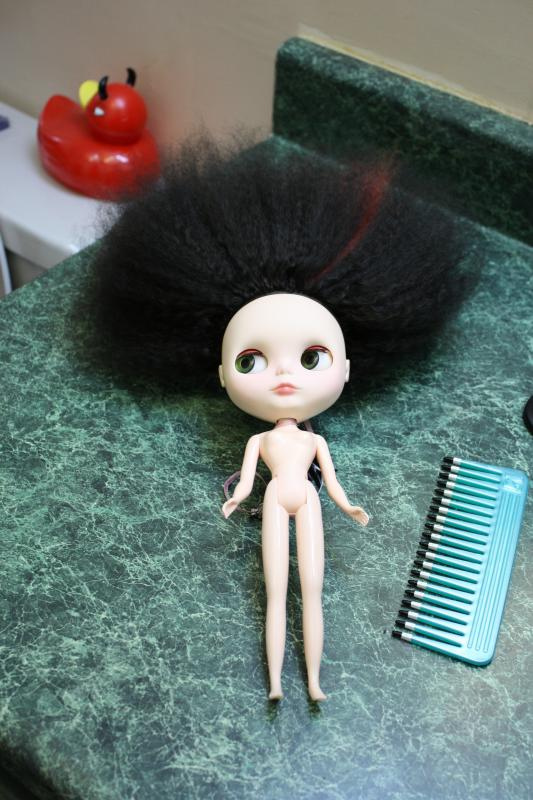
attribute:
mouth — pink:
[272, 378, 298, 393]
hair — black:
[53, 129, 494, 426]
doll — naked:
[63, 113, 503, 716]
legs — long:
[249, 485, 297, 711]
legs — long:
[297, 482, 334, 707]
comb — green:
[391, 472, 531, 678]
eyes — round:
[229, 343, 272, 380]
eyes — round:
[295, 342, 342, 379]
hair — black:
[65, 118, 490, 409]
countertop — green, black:
[1, 132, 531, 795]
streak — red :
[330, 166, 395, 280]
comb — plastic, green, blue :
[394, 457, 530, 670]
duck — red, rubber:
[31, 67, 172, 206]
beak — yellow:
[76, 80, 102, 106]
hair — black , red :
[74, 127, 472, 425]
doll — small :
[97, 140, 443, 720]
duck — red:
[38, 65, 164, 201]